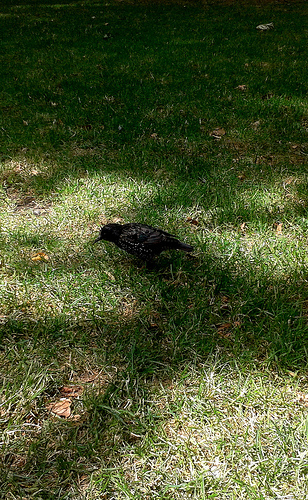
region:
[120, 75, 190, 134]
patch of green grass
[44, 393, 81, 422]
brown leaf on green grass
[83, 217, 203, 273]
black bird standing on green grass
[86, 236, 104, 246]
black beak of bird in grass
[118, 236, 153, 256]
spotted chest feathers of black bird in grass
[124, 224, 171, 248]
wing of black bird in grass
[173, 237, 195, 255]
black tail feathers of bird in grass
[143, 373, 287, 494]
ray of sunlight on green grass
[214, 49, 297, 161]
many fallen brown leaves on grass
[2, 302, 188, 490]
v shaped dark shadow on grass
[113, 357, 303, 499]
A patch of sunlight on shadowy ground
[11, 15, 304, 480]
Green grass with a bird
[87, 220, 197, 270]
A black bird searching the ground for food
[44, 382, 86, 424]
Brown leaf fallen from a tree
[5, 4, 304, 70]
Grass lawn in deep shadow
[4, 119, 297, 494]
Shadows and dappled sunlight on a lawn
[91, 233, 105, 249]
Bird beak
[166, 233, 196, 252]
Feather tail of a bird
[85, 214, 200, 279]
A black bird resting in the grass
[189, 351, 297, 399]
Stalks of green grass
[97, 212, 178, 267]
A black bird in grass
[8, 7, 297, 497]
a grassy field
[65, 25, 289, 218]
leaves scattered in the grass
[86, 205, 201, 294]
a crow in the grass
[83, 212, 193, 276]
a raven in the grass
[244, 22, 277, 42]
a dead leaf in the grass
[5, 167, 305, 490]
The sun shining on the grass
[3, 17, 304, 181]
A large shaded area of grass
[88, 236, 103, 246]
the beak of the bird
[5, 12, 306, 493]
dead leaves from trees above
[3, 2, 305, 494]
a scene outside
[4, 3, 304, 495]
a scene during the day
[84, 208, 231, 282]
a black bird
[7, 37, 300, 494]
a patch of grass is here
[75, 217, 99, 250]
a bird's beak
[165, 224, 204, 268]
a bird's tail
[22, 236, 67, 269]
a yellow leaf is here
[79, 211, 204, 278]
a bird standing here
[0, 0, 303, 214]
a shadow is here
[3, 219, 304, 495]
green grass is here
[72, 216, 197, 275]
Small black bird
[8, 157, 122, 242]
Sun shinning on the grass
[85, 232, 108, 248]
Black beak of a bird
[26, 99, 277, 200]
Large grass area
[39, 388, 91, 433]
Brown leaf laying in the grass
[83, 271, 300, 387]
Shadown from tree above the grass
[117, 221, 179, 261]
Feathers of a black bird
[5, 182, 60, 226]
Small dirt patch in the grass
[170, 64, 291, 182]
Scattered leaves on the ground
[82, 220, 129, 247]
Small head of a black bird